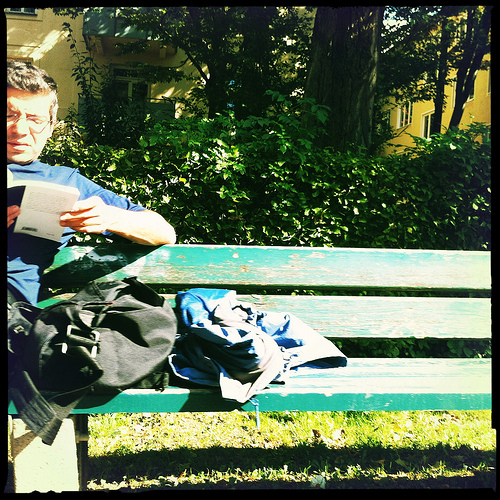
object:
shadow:
[9, 428, 498, 492]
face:
[7, 88, 59, 165]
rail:
[37, 242, 494, 375]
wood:
[8, 242, 492, 421]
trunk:
[208, 52, 230, 117]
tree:
[62, 0, 490, 209]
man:
[6, 56, 175, 448]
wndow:
[78, 92, 175, 147]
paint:
[383, 51, 491, 164]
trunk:
[431, 22, 453, 138]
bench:
[7, 243, 491, 495]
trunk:
[304, 1, 388, 146]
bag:
[0, 274, 179, 447]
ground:
[6, 409, 496, 491]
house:
[2, 0, 491, 168]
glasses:
[7, 109, 53, 134]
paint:
[191, 243, 253, 283]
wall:
[386, 52, 492, 160]